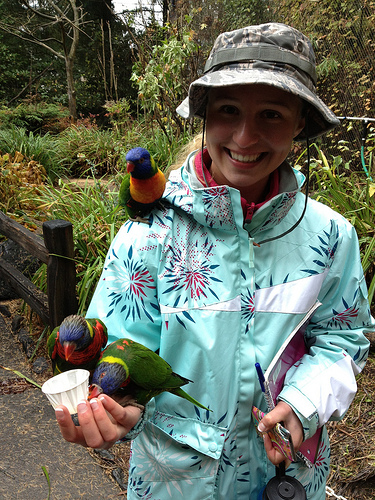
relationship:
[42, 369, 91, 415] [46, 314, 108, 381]
paper cup near bird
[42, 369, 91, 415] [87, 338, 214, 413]
paper cup near bird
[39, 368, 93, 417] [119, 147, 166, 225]
paper cup feeds bird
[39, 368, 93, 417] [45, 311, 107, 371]
paper cup feeds lorikeet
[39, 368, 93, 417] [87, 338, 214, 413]
paper cup feeds bird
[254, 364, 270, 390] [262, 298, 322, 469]
ink pen with book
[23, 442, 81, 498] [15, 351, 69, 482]
stone on ground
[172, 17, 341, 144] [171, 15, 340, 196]
hat on head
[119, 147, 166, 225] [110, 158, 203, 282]
bird on shoulder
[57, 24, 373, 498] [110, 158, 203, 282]
girl has shoulder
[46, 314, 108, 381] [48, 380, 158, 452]
bird on hand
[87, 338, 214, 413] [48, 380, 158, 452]
bird on hand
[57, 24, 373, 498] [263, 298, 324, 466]
girl holds book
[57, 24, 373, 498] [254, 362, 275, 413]
girl holds ink pen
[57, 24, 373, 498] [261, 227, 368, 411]
girl has arm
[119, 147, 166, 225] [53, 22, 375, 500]
bird sitting on girl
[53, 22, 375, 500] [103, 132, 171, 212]
girl holding bird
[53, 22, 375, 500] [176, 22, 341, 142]
girl wearing hat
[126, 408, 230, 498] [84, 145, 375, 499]
pocket on coat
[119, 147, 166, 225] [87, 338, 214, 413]
bird on bird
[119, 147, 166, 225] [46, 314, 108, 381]
bird on bird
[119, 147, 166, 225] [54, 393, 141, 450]
bird on hand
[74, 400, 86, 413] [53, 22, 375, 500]
nail on girl